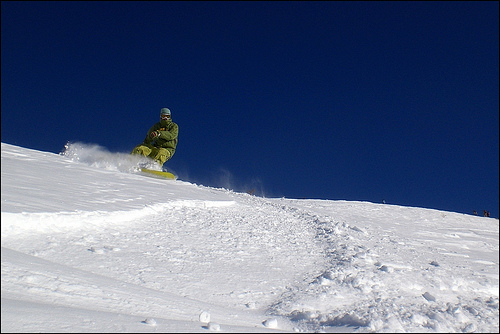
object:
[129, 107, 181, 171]
man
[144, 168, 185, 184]
board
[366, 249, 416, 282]
snow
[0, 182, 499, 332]
ground